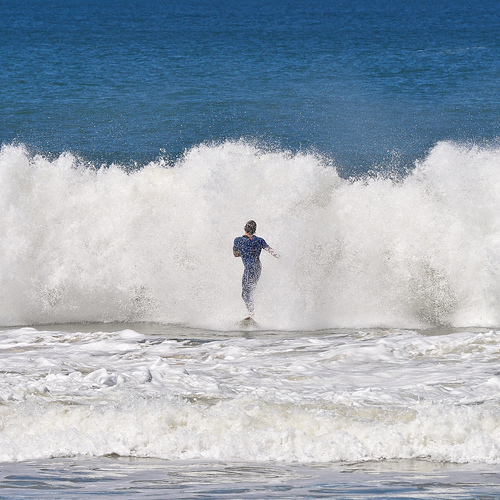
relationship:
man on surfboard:
[232, 219, 282, 318] [232, 315, 262, 330]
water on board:
[0, 2, 500, 500] [233, 311, 268, 331]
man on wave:
[232, 219, 282, 318] [4, 137, 499, 337]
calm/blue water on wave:
[3, 0, 489, 112] [2, 130, 499, 362]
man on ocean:
[232, 219, 282, 318] [3, 318, 498, 490]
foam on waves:
[72, 390, 354, 477] [74, 170, 322, 392]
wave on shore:
[4, 137, 499, 337] [1, 340, 498, 494]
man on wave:
[225, 212, 291, 337] [4, 137, 499, 337]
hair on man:
[244, 220, 256, 232] [224, 216, 279, 323]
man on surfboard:
[232, 219, 282, 318] [241, 317, 259, 332]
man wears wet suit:
[232, 219, 282, 318] [228, 231, 270, 314]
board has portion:
[231, 305, 271, 332] [334, 255, 394, 310]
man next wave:
[232, 219, 282, 318] [2, 389, 498, 466]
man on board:
[232, 219, 282, 318] [235, 316, 262, 332]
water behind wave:
[2, 2, 499, 184] [19, 172, 228, 300]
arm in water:
[260, 235, 282, 265] [276, 216, 408, 286]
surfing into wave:
[234, 306, 269, 345] [4, 137, 499, 337]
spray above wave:
[352, 130, 410, 175] [11, 144, 482, 324]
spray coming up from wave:
[7, 124, 488, 195] [91, 223, 431, 325]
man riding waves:
[232, 219, 282, 318] [5, 263, 488, 406]